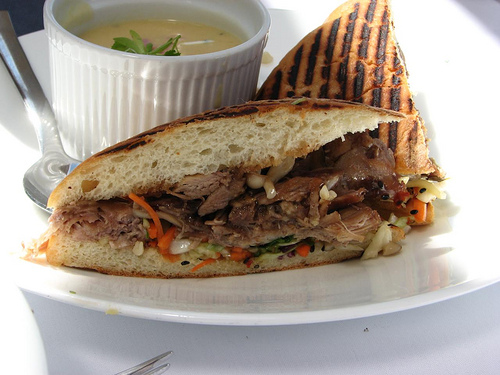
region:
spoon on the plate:
[2, 14, 91, 227]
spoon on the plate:
[11, 29, 96, 225]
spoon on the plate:
[4, 30, 119, 275]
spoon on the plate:
[8, 35, 110, 227]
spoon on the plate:
[4, 54, 96, 244]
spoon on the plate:
[8, 30, 88, 242]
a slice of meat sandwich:
[64, 104, 393, 286]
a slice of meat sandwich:
[47, 92, 385, 290]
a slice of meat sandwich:
[37, 90, 382, 272]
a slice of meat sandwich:
[39, 92, 377, 292]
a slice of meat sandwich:
[59, 103, 433, 328]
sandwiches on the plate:
[51, 26, 443, 276]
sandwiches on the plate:
[45, 39, 489, 291]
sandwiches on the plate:
[30, 26, 446, 300]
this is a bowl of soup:
[33, 2, 275, 169]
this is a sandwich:
[25, 92, 407, 284]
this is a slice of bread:
[50, 89, 400, 182]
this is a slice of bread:
[38, 208, 423, 296]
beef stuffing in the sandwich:
[60, 145, 417, 238]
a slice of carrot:
[122, 185, 168, 240]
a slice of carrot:
[149, 217, 182, 265]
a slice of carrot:
[216, 237, 258, 282]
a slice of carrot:
[296, 237, 316, 268]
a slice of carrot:
[403, 192, 441, 234]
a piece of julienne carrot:
[126, 190, 163, 238]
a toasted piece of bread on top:
[51, 100, 396, 200]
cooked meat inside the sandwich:
[77, 170, 364, 255]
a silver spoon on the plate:
[0, 10, 85, 218]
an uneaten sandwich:
[47, 95, 412, 271]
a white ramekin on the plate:
[43, 3, 270, 165]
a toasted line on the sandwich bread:
[317, 20, 338, 97]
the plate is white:
[0, 14, 499, 325]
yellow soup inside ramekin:
[78, 15, 245, 59]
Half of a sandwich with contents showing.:
[40, 97, 410, 284]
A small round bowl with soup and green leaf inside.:
[40, 1, 270, 163]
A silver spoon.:
[0, 11, 85, 216]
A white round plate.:
[0, 1, 498, 326]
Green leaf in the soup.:
[112, 28, 183, 58]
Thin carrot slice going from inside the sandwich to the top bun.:
[126, 190, 163, 242]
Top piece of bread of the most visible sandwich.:
[46, 99, 409, 211]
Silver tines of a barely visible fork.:
[113, 353, 172, 373]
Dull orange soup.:
[79, 19, 244, 56]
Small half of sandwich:
[37, 101, 402, 278]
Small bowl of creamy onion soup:
[38, 0, 270, 162]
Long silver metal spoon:
[0, 11, 82, 213]